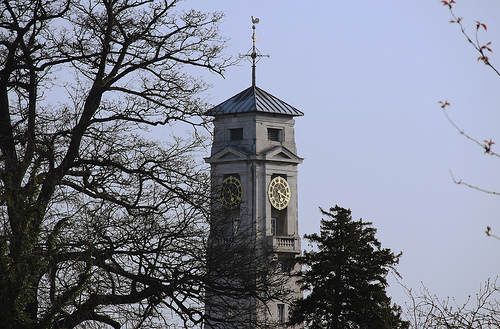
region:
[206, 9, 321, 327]
gray clock tower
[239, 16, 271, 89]
decorative rod on the top of the tower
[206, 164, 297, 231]
clocks on either side of the tower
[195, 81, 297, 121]
blue roof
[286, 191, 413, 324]
top of a tree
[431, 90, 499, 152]
skinny branch with a few leaves on it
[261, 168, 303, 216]
clock indicating that it's about 4:20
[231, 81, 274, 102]
black spot on the blue roof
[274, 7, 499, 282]
light blue sky with no clouds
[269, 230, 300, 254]
balcony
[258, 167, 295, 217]
The clock is on top of the tower.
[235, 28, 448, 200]
The sky is clear and blue.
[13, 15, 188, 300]
The tree is bare.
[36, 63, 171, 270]
Branches on the tree.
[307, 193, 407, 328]
A green tree by the tower.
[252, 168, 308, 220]
The clock has a white face.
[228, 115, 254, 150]
A window on the top of the tower.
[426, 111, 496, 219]
Bare branches on the side.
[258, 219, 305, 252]
The tower has a balcony.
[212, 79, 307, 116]
The roof is shaped like a triangle.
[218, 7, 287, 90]
weather vane on roof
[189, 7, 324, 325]
large stone clock tower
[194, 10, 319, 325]
clock tower with metal roof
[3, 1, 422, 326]
large trees near clock tower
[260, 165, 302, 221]
large clock with gold dials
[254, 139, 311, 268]
balcony on a clock tower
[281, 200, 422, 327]
small green pine tree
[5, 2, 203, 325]
large tree with no leaves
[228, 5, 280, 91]
rooster design on weather vane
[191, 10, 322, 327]
large stone tower with gold clocks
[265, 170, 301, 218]
a clock attached to a tower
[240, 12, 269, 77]
rooster and cross on top of a tower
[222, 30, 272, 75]
a rooster ole indicating the wind direction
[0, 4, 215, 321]
a huge tree on the left side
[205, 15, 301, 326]
a high monument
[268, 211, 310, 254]
a small balcony on the tower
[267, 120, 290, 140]
a rectangular window at the top of a tower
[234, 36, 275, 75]
a sign on top of a tower point south.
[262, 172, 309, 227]
a clock indicating that it's 5:18pm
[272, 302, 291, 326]
a small door at the bottom of the tower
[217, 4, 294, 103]
a compass on the top on the clock tower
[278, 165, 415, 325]
the top of a green tree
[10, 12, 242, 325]
branches of a brown tree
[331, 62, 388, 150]
clear light blue sky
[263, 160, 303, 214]
round clock on the tower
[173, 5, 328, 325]
tall gray clock tower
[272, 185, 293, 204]
hands on the clock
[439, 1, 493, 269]
thin brown branches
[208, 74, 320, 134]
blue roof of the clock tower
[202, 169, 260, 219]
clock on the other side